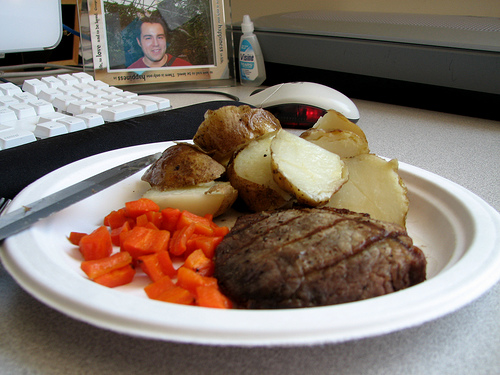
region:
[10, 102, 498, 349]
A white plate with meat, potatoes, and carrots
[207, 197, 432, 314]
A piece of meat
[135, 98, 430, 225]
Roasted white potatoes with the skins on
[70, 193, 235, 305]
A small portion of carrots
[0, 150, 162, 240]
A stainless steel steak knife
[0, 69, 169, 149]
A portion of a computer keyboard with white keys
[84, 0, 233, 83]
A man's photo in a metal frame with engraving along the sides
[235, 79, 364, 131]
A white computer mouse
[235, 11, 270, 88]
A bottle of Visine eyedrops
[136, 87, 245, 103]
The black tail of a computer mouse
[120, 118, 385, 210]
a baked potato on a plate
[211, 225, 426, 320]
a hamburger steak on a plate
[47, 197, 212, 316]
cooked carrots on a plate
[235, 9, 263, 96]
a plastic bottle of eye medicine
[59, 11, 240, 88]
a framed picture on a table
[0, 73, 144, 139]
a white computer keyboard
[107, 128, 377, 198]
a cut baked potato on a plate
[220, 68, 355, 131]
a white computer mouse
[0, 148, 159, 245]
a knife on a white plate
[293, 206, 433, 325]
cooked meat on a plate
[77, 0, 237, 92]
picture in glass frame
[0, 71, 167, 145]
white buttons on keyboard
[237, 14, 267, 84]
plastic bottle with label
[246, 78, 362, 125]
mouse with white top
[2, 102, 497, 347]
food on white plate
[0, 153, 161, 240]
silver blade of knife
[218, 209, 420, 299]
steak with grill marks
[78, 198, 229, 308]
pieces of cooked carrots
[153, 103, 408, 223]
potato chunks with skin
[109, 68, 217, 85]
words on picture frame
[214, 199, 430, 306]
beef on the plate.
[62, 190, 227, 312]
Carrots on the plate.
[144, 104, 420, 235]
Potatoes on the plate.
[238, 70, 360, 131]
mouse on the desk.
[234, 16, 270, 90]
bottle on the desk.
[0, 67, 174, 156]
keyboard on the desk.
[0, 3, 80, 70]
monitor on the desk.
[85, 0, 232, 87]
Picture on the desk.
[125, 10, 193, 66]
Man in the picture.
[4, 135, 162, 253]
Knife on the plate.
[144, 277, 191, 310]
a piece of orange carrot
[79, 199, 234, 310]
small pieces of carrot on plate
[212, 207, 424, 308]
round grilled meat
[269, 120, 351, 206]
a piece of potato with skin on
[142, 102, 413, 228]
pieces of potato on plate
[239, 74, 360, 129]
a black and white computer mouse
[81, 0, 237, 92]
a photo of a man in frame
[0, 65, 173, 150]
a white computer keyboard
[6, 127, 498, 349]
white round disposable plate full of food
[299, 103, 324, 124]
red light on computer mouse